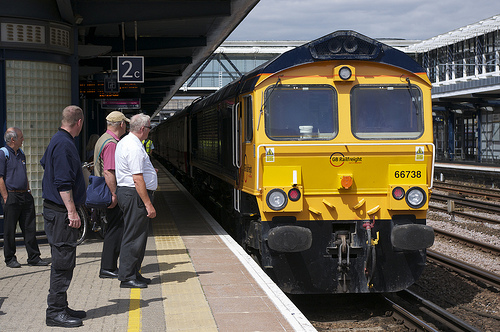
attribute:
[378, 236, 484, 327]
rails — train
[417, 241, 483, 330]
tracks — train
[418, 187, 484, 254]
tracks — train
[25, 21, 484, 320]
station — train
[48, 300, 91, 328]
shoes — black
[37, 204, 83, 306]
pant — black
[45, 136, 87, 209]
shirt — blue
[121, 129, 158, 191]
shirt — white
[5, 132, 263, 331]
ground — concrete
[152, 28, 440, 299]
train — black, yellow, arriving, commuter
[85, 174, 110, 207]
bag — blue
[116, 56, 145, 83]
sign — hanging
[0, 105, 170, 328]
people — waiting, standing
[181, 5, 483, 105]
sky — cloudy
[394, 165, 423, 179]
number — 66738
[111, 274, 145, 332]
line — yellow